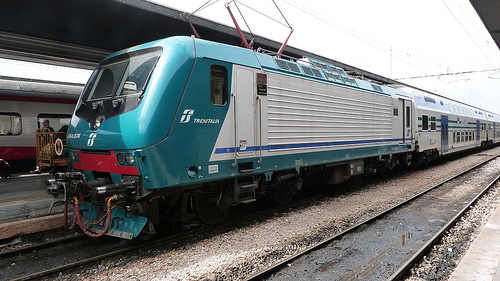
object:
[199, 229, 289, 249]
gravel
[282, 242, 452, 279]
tracks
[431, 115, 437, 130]
window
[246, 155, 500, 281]
train track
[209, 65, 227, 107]
window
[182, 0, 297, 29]
wires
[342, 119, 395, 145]
ground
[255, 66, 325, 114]
ground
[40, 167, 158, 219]
bumper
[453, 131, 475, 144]
windows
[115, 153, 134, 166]
light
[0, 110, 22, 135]
window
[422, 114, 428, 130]
window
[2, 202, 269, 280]
train track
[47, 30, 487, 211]
train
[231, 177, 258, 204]
steps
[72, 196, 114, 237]
red hose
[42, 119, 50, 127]
head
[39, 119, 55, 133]
man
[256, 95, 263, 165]
rail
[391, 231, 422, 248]
puddle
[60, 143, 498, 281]
rocks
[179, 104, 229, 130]
logo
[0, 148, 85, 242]
platform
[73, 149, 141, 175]
trim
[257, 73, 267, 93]
window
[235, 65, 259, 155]
door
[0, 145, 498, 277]
ground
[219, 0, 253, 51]
frame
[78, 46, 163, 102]
window